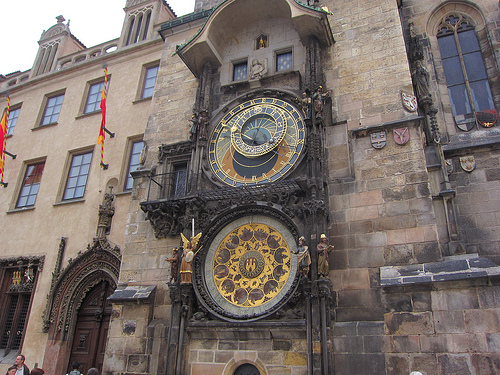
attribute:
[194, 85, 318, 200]
clock — gold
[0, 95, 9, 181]
flag — still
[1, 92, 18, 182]
flag — red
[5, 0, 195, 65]
sky — cloudless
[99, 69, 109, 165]
flag — red, yellow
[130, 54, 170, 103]
window — closed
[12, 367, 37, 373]
jacket — dark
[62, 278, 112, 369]
door — wooden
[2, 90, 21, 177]
flag — orange, yellow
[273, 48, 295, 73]
window — closed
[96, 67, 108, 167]
flag — rolled-up, red, yellow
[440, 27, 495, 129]
window — closed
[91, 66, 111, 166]
flag — yellow, red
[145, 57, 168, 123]
window — closed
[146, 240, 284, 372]
door — wooden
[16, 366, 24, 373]
shirt — blue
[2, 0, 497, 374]
building — stone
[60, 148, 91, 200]
window — closed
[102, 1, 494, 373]
building — brown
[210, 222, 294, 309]
ornate medallion — gold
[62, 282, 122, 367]
door — wooden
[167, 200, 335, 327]
shield — coats of arms